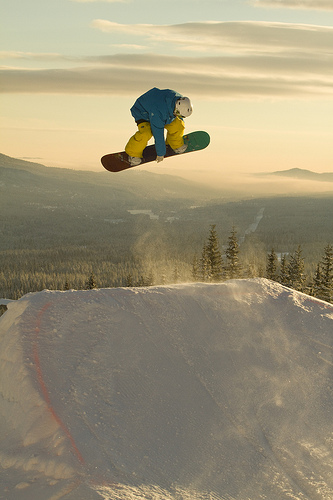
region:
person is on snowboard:
[96, 62, 220, 167]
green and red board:
[112, 120, 193, 179]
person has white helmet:
[134, 96, 192, 132]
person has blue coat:
[142, 87, 176, 127]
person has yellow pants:
[136, 104, 188, 153]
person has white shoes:
[128, 137, 186, 170]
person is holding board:
[107, 124, 199, 186]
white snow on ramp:
[35, 266, 286, 439]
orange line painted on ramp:
[34, 297, 72, 485]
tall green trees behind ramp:
[188, 221, 331, 326]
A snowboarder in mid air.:
[97, 83, 211, 172]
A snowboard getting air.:
[97, 84, 211, 171]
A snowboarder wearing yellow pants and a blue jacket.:
[95, 83, 212, 172]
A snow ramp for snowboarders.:
[3, 276, 329, 488]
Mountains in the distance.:
[2, 171, 331, 241]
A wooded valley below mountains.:
[3, 225, 330, 275]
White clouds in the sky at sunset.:
[1, 7, 326, 82]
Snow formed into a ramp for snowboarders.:
[8, 275, 322, 498]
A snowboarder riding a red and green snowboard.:
[98, 84, 212, 172]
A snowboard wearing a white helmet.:
[99, 84, 212, 174]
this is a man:
[114, 91, 202, 166]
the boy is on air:
[104, 85, 206, 172]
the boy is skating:
[101, 82, 207, 175]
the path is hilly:
[55, 277, 227, 401]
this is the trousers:
[127, 126, 151, 154]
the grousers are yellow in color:
[125, 127, 149, 153]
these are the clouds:
[253, 24, 303, 82]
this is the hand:
[153, 125, 168, 157]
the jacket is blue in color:
[140, 95, 169, 119]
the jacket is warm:
[141, 92, 169, 117]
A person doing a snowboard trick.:
[86, 71, 223, 188]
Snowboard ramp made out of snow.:
[6, 280, 325, 492]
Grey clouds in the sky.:
[5, 21, 322, 108]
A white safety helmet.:
[170, 86, 195, 117]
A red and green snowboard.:
[99, 129, 219, 173]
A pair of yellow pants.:
[122, 112, 191, 155]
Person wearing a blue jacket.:
[122, 84, 194, 161]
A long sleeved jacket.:
[125, 75, 177, 160]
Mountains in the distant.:
[2, 137, 325, 283]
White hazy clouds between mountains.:
[161, 162, 332, 202]